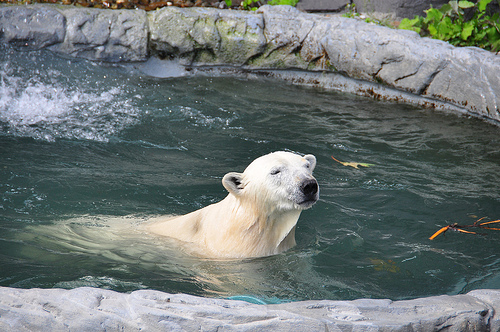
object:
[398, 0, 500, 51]
leaves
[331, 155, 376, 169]
leaf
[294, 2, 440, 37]
wall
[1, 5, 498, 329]
tub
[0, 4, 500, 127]
containment wall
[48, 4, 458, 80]
stone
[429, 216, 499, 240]
item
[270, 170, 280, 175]
eyes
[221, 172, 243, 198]
ear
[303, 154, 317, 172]
ear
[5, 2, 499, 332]
pool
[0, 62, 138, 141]
churning water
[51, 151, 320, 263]
bear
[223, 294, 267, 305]
object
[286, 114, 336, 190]
floor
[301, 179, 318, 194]
nose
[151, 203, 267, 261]
fur